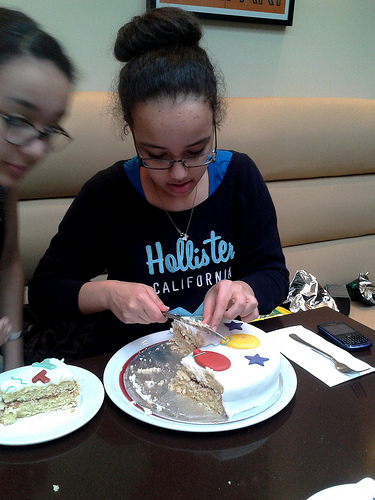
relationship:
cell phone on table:
[309, 307, 374, 351] [295, 277, 351, 333]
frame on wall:
[197, 1, 319, 34] [2, 0, 374, 98]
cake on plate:
[134, 301, 244, 411] [73, 298, 289, 442]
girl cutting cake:
[32, 6, 290, 359] [165, 304, 285, 418]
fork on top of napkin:
[287, 330, 368, 376] [265, 324, 373, 391]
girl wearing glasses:
[32, 6, 290, 359] [125, 140, 216, 170]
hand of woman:
[198, 277, 259, 332] [30, 6, 289, 329]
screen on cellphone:
[323, 321, 350, 334] [318, 318, 373, 352]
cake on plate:
[147, 303, 285, 425] [96, 316, 311, 440]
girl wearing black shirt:
[32, 6, 290, 359] [27, 149, 288, 362]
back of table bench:
[328, 228, 363, 242] [19, 91, 374, 332]